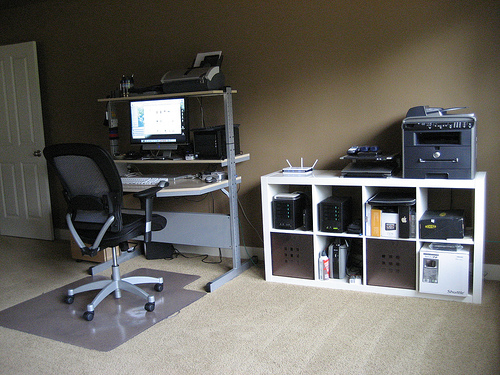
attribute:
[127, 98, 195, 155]
screen — large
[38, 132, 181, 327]
chair — black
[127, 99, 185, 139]
computer monitor — bright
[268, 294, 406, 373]
carpet — tan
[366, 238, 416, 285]
storage box — brown, plastic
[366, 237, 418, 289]
storage box — brown 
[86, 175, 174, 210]
computer keyboard — white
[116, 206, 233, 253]
bottom — silver, metal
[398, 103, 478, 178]
printer — black